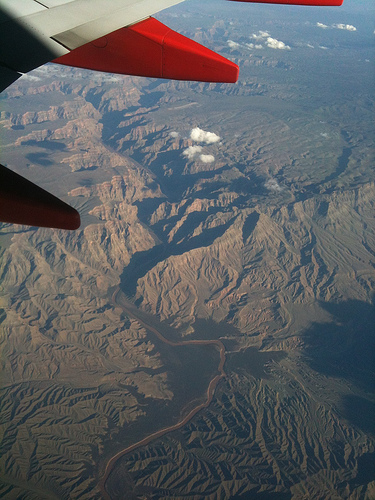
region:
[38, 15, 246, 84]
a red plane engine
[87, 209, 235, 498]
a brown river down below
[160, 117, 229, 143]
a white cloud in the sky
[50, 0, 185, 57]
a landing flap on the plane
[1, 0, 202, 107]
the wing of a plane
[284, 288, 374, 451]
shadows on the mountains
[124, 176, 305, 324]
a mountain under the clouds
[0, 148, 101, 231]
a shadowed red engine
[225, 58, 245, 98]
the rear tip of an engine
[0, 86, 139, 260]
a flat mesa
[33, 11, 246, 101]
The wing is red.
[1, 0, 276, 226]
The airplane is in the air.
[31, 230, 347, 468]
The ground is brown.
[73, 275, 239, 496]
There's a trail through the mountains.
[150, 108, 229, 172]
The clouds are white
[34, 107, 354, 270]
The ground is bumpy.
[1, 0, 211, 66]
The plane is white.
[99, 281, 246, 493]
The trail is brown.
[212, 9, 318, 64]
Small clusters of clouds.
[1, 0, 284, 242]
The wing is large.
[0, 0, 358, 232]
airplane wing in the sky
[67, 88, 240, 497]
river weaving thru terrain below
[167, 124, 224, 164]
clouds floating in the sky below plane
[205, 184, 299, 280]
highest mountain peak in shot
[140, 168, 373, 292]
mountain ridge across right of picture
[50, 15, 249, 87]
orange part of plane wing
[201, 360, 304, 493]
green and brown terrain colors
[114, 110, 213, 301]
shadows cast by the mountain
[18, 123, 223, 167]
clouds casting shadows on the terrain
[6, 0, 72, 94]
gaps in air plane wing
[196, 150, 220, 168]
a cloud in the sky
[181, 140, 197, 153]
a cloud in the sky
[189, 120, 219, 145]
a cloud in the sky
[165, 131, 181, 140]
a cloud in the sky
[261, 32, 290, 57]
a cloud in the sky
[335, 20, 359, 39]
a cloud in the sky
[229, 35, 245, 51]
a cloud in the sky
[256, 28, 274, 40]
a cloud in the sky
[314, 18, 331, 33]
a cloud in the sky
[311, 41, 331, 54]
a cloud in the sky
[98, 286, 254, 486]
river in photo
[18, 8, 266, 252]
red and white plane partially pictured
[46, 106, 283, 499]
mountainous terrain in photo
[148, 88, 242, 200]
few clouds in photo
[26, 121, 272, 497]
brown barren landscape in photo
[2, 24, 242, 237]
red wings of plane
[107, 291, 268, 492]
muddy water of river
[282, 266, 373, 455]
shadow in photo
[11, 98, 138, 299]
tops of cliffs in photo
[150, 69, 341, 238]
round shaped field in photo